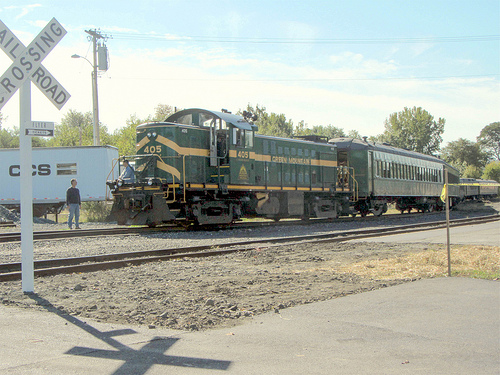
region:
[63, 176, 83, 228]
a man standing beside railroad tracks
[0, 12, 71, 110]
a traffic railroad crossing sign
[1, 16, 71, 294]
a railroad crossing sign on a pole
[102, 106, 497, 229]
a parked green train with yellow stripes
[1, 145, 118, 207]
the backside of a white trailer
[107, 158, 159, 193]
a man sitting on the train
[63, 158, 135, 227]
two men taking to each other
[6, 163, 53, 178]
"CCS" on the side of the trailer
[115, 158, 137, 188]
a driver of the train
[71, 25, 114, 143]
a utility and light pole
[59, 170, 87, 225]
man standing by train tracks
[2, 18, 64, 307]
white railroad crossing sign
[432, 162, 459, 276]
yellow flag on a stick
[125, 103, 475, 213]
train on train tracks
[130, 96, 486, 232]
train stopped on tracks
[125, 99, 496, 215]
green train with yellow line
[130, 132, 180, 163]
numbers on front of train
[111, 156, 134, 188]
man sitting on front of train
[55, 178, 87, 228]
man wearing long sleeve shirt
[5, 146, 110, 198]
white train car in dirt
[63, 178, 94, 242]
a person standing next to the train tracks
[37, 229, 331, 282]
the train tracks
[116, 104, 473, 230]
a train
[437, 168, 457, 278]
a sign next to the train tracks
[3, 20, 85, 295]
a railroad crossing sign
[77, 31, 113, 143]
a telephone pole behind the train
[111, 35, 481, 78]
wires coming off the telephone pole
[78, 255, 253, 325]
dirt next to the train tracks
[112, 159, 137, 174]
a person sitting on the train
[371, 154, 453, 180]
windows on the train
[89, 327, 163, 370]
a shadow on the ground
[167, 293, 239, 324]
rocks in the dirt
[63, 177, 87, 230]
a person standing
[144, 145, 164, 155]
numbers on the train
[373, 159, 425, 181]
windows on the train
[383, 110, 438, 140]
the bush is green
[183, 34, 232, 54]
the electrical lines in the sky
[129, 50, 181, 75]
the clouds are white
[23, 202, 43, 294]
a pole that is white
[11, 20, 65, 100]
white railroad crossing sign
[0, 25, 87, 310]
sign on white pole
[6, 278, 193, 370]
shadow cast on road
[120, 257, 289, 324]
gravel next to track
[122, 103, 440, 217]
green and yellow train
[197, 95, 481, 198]
green trees behind train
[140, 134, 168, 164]
yellow numbers on train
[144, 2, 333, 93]
blue and white sky